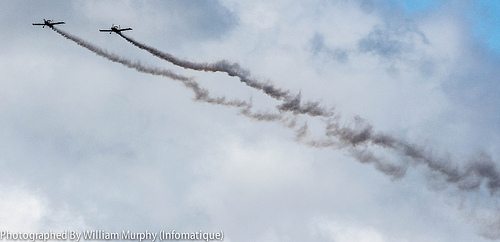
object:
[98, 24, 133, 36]
plane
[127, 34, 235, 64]
trail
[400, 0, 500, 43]
blue spot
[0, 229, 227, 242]
tag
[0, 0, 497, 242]
image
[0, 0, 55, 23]
dark spot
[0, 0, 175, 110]
top left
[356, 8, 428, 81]
wispy cloud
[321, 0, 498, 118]
top right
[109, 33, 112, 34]
wheels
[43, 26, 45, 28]
wheels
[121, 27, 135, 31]
wings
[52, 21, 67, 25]
wings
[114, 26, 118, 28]
engine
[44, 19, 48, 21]
engine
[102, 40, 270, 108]
smoke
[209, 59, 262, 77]
vapor trails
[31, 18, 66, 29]
planes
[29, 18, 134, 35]
dogfight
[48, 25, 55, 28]
gear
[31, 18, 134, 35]
together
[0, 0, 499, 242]
air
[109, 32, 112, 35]
legs down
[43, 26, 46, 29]
legs down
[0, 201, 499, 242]
bottom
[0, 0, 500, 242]
sky